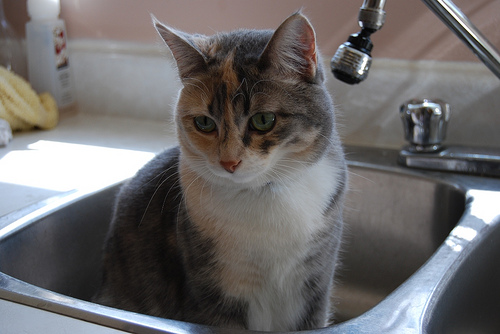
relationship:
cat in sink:
[113, 16, 339, 323] [2, 160, 470, 333]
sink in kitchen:
[2, 160, 470, 333] [1, 2, 499, 331]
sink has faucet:
[2, 160, 470, 333] [332, 3, 500, 173]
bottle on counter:
[23, 3, 78, 117] [3, 106, 181, 221]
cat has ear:
[113, 16, 339, 323] [265, 10, 320, 79]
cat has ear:
[113, 16, 339, 323] [153, 20, 212, 79]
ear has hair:
[265, 10, 320, 79] [282, 35, 307, 82]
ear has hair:
[153, 20, 212, 79] [167, 41, 194, 68]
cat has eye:
[113, 16, 339, 323] [245, 108, 284, 138]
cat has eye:
[113, 16, 339, 323] [190, 108, 222, 140]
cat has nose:
[113, 16, 339, 323] [219, 159, 245, 174]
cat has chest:
[113, 16, 339, 323] [180, 160, 366, 297]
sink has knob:
[2, 160, 470, 333] [397, 89, 453, 161]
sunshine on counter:
[7, 137, 159, 192] [3, 106, 181, 221]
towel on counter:
[2, 66, 63, 130] [3, 106, 181, 221]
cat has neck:
[113, 16, 339, 323] [194, 164, 330, 199]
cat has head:
[113, 16, 339, 323] [144, 17, 368, 185]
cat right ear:
[87, 10, 349, 332] [259, 12, 319, 86]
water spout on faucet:
[330, 25, 379, 85] [355, 0, 498, 79]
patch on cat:
[176, 158, 343, 332] [90, 31, 407, 316]